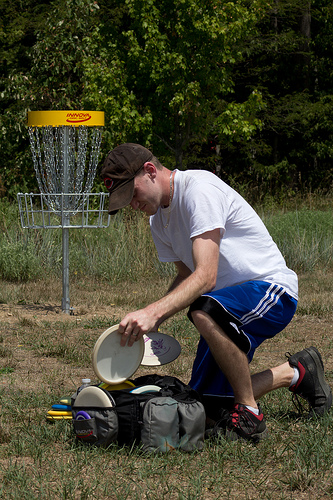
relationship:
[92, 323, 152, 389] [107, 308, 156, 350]
frisbee in hand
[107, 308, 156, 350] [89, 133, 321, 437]
hand of man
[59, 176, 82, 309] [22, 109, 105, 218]
pole with device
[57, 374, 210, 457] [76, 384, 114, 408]
bag with frisbees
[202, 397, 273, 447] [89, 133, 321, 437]
shoe on man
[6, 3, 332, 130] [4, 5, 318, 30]
trees in background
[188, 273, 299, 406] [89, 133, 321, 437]
shorts on man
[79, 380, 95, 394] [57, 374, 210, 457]
bottle poking out bag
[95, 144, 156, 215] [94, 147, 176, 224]
hat on head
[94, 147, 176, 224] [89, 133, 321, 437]
head of man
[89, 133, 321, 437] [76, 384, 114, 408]
man has frisbees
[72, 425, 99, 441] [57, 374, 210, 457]
logo on bag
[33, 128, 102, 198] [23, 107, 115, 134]
chains of disk catcher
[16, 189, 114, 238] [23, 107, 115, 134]
basket of disk catcher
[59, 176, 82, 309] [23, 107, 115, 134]
pole holding disk catcher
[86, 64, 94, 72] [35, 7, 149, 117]
leaf on tree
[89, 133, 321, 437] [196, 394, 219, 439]
he on knee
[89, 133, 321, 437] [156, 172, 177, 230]
he wearing necklace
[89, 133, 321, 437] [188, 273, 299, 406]
man in shorts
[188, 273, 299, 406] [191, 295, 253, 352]
shorts with trim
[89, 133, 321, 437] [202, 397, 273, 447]
man wearing shoe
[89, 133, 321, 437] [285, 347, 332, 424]
man wearing shoe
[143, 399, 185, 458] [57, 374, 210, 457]
pouch of bag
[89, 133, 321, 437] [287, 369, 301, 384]
man wears socks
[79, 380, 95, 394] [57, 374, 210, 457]
bottle in bag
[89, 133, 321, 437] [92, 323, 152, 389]
man holding plate